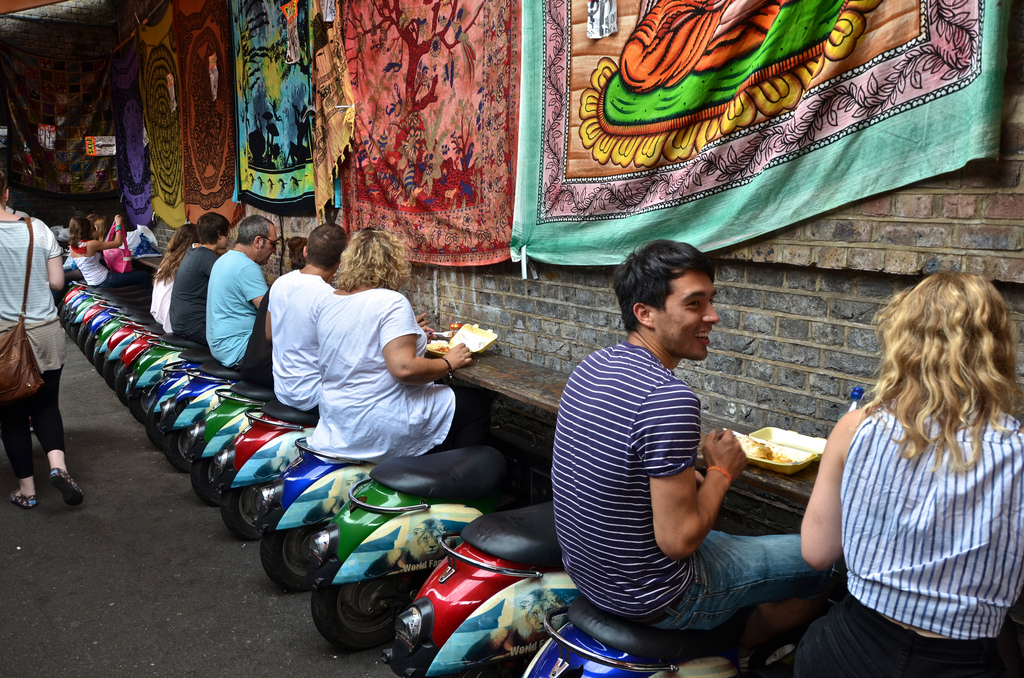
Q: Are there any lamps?
A: No, there are no lamps.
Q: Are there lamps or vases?
A: No, there are no lamps or vases.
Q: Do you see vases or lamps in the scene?
A: No, there are no lamps or vases.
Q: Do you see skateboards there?
A: No, there are no skateboards.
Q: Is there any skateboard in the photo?
A: No, there are no skateboards.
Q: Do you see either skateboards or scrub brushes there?
A: No, there are no skateboards or scrub brushes.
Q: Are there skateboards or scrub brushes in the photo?
A: No, there are no skateboards or scrub brushes.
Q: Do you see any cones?
A: No, there are no cones.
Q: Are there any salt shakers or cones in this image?
A: No, there are no cones or salt shakers.